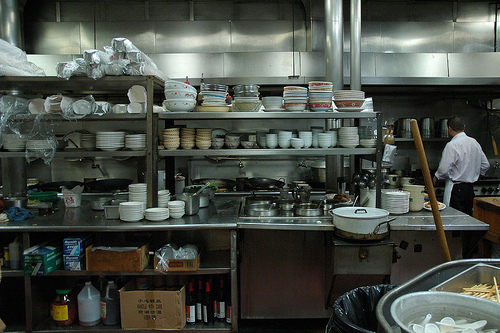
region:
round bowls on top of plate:
[341, 89, 362, 114]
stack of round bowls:
[311, 83, 331, 113]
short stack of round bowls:
[285, 81, 307, 116]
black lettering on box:
[126, 295, 170, 322]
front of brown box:
[102, 250, 128, 269]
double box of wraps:
[61, 236, 83, 273]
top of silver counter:
[59, 208, 81, 222]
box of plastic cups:
[161, 246, 188, 257]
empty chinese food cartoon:
[56, 183, 86, 208]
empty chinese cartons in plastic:
[42, 94, 70, 115]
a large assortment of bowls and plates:
[3, 78, 386, 204]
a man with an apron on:
[437, 116, 494, 217]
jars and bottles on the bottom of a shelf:
[39, 283, 109, 323]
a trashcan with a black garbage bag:
[330, 284, 385, 330]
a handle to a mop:
[401, 112, 446, 260]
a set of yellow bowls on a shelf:
[161, 128, 211, 151]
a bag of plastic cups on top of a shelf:
[67, 41, 163, 75]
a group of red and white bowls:
[278, 76, 367, 111]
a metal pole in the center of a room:
[314, 5, 369, 88]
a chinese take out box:
[55, 183, 83, 213]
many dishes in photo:
[143, 70, 363, 160]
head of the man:
[430, 97, 480, 142]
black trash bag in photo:
[325, 277, 385, 328]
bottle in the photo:
[60, 270, 105, 325]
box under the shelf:
[130, 270, 191, 330]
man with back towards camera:
[425, 110, 485, 186]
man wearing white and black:
[416, 105, 481, 186]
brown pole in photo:
[398, 108, 463, 252]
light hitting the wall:
[393, 24, 454, 63]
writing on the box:
[131, 285, 172, 332]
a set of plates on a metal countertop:
[387, 181, 423, 211]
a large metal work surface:
[21, 206, 332, 231]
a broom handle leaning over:
[404, 113, 456, 260]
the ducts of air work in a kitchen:
[364, 17, 496, 87]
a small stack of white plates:
[92, 129, 125, 152]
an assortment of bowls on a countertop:
[121, 203, 193, 225]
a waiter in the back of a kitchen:
[434, 109, 495, 210]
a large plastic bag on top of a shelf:
[1, 42, 42, 82]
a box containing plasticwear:
[153, 244, 200, 276]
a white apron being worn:
[439, 182, 460, 207]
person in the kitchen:
[423, 107, 486, 197]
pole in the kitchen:
[398, 112, 464, 279]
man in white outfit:
[413, 104, 486, 205]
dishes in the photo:
[102, 41, 392, 207]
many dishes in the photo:
[154, 59, 369, 184]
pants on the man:
[448, 172, 483, 217]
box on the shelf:
[108, 273, 196, 332]